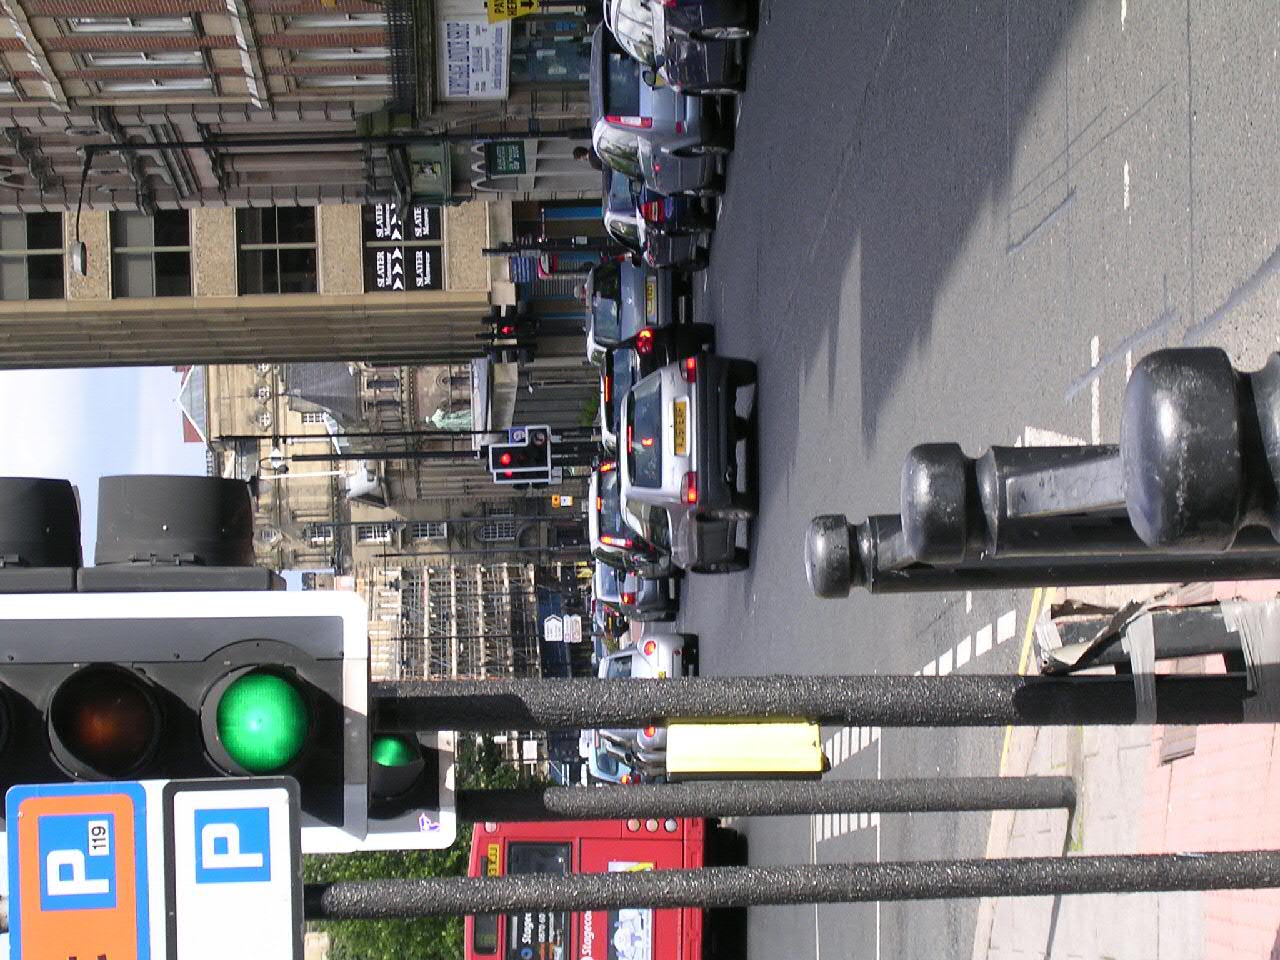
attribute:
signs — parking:
[33, 724, 426, 948]